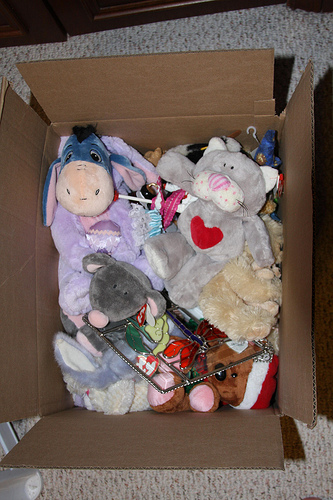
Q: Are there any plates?
A: No, there are no plates.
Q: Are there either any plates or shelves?
A: No, there are no plates or shelves.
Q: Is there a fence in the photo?
A: No, there are no fences.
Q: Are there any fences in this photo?
A: No, there are no fences.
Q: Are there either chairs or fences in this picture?
A: No, there are no fences or chairs.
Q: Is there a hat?
A: Yes, there is a hat.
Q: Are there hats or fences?
A: Yes, there is a hat.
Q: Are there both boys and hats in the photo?
A: No, there is a hat but no boys.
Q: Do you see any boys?
A: No, there are no boys.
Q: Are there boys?
A: No, there are no boys.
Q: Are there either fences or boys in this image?
A: No, there are no boys or fences.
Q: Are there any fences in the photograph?
A: No, there are no fences.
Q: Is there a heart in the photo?
A: Yes, there is a heart.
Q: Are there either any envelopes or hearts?
A: Yes, there is a heart.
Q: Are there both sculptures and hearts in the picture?
A: No, there is a heart but no sculptures.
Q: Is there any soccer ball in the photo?
A: No, there are no soccer balls.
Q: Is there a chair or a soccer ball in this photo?
A: No, there are no soccer balls or chairs.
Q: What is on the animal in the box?
A: The heart is on the animal.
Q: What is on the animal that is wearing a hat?
A: The heart is on the animal.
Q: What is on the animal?
A: The heart is on the animal.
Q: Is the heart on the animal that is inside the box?
A: Yes, the heart is on the animal.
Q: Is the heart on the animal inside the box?
A: Yes, the heart is on the animal.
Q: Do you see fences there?
A: No, there are no fences.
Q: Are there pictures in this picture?
A: No, there are no pictures.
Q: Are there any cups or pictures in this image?
A: No, there are no pictures or cups.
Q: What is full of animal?
A: The box is full of animal.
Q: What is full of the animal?
A: The box is full of animal.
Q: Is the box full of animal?
A: Yes, the box is full of animal.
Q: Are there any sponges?
A: No, there are no sponges.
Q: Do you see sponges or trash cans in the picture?
A: No, there are no sponges or trash cans.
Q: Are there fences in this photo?
A: No, there are no fences.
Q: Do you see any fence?
A: No, there are no fences.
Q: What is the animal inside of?
A: The animal is inside the box.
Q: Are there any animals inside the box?
A: Yes, there is an animal inside the box.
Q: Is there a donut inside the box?
A: No, there is an animal inside the box.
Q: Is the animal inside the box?
A: Yes, the animal is inside the box.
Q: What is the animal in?
A: The animal is in the box.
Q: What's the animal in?
A: The animal is in the box.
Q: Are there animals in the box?
A: Yes, there is an animal in the box.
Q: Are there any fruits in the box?
A: No, there is an animal in the box.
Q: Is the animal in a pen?
A: No, the animal is in a box.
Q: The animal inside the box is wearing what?
A: The animal is wearing a hat.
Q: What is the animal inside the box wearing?
A: The animal is wearing a hat.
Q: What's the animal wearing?
A: The animal is wearing a hat.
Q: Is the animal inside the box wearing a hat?
A: Yes, the animal is wearing a hat.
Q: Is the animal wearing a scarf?
A: No, the animal is wearing a hat.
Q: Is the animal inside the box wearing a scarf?
A: No, the animal is wearing a hat.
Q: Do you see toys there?
A: Yes, there is a toy.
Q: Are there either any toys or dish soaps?
A: Yes, there is a toy.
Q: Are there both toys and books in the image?
A: No, there is a toy but no books.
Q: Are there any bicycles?
A: No, there are no bicycles.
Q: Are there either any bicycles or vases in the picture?
A: No, there are no bicycles or vases.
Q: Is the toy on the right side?
A: Yes, the toy is on the right of the image.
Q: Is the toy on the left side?
A: No, the toy is on the right of the image.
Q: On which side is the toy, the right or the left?
A: The toy is on the right of the image.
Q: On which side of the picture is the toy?
A: The toy is on the right of the image.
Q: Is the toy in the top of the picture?
A: Yes, the toy is in the top of the image.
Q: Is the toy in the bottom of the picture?
A: No, the toy is in the top of the image.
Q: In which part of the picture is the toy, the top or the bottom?
A: The toy is in the top of the image.